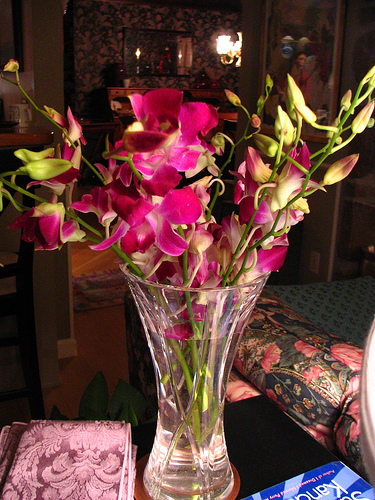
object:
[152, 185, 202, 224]
petal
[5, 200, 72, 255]
flower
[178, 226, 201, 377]
stem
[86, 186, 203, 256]
flower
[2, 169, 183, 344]
stem